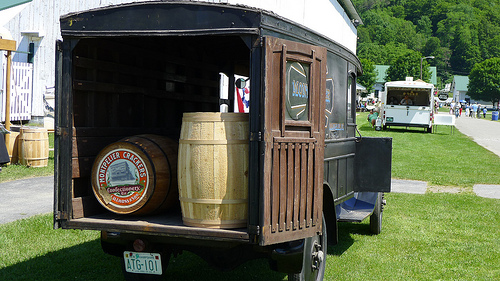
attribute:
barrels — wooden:
[90, 106, 225, 233]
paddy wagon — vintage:
[62, 61, 342, 263]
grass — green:
[411, 215, 442, 255]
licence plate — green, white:
[108, 243, 177, 279]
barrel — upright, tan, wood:
[175, 98, 252, 228]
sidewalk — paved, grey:
[457, 109, 495, 165]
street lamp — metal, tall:
[417, 48, 449, 98]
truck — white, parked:
[372, 72, 433, 149]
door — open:
[71, 74, 280, 231]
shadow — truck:
[31, 247, 77, 278]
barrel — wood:
[15, 129, 53, 186]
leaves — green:
[380, 52, 431, 80]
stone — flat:
[406, 170, 430, 202]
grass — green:
[395, 129, 455, 197]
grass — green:
[415, 135, 455, 276]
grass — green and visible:
[411, 213, 462, 277]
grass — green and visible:
[418, 140, 477, 177]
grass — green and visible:
[0, 226, 72, 279]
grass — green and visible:
[342, 238, 404, 278]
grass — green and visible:
[389, 126, 464, 151]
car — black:
[51, 0, 393, 279]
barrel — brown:
[87, 129, 177, 216]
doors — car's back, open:
[54, 37, 324, 247]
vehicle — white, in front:
[375, 74, 435, 131]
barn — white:
[2, 0, 362, 137]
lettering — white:
[95, 150, 145, 180]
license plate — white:
[120, 247, 164, 277]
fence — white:
[5, 59, 33, 124]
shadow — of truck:
[1, 236, 291, 277]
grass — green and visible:
[397, 207, 459, 277]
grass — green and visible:
[415, 132, 464, 177]